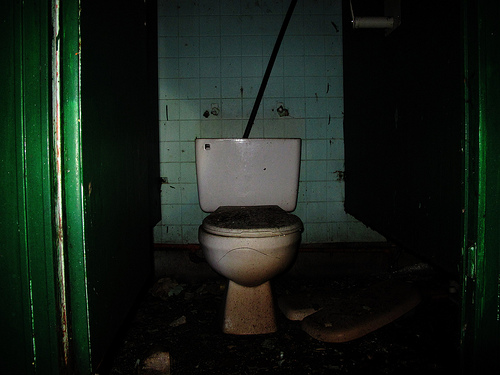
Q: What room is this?
A: It is a bathroom.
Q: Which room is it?
A: It is a bathroom.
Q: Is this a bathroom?
A: Yes, it is a bathroom.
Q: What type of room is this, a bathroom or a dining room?
A: It is a bathroom.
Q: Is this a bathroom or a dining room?
A: It is a bathroom.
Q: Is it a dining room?
A: No, it is a bathroom.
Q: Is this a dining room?
A: No, it is a bathroom.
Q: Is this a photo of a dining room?
A: No, the picture is showing a bathroom.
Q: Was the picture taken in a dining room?
A: No, the picture was taken in a bathroom.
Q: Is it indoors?
A: Yes, it is indoors.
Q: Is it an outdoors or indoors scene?
A: It is indoors.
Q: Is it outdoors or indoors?
A: It is indoors.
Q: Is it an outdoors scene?
A: No, it is indoors.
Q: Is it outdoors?
A: No, it is indoors.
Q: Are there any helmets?
A: No, there are no helmets.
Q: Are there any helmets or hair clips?
A: No, there are no helmets or hair clips.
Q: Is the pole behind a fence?
A: No, the pole is behind a toilet.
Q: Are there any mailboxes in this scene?
A: No, there are no mailboxes.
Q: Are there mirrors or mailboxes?
A: No, there are no mailboxes or mirrors.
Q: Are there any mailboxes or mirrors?
A: No, there are no mailboxes or mirrors.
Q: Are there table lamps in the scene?
A: No, there are no table lamps.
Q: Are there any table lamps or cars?
A: No, there are no table lamps or cars.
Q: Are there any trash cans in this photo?
A: No, there are no trash cans.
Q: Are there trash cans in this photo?
A: No, there are no trash cans.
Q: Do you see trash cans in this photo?
A: No, there are no trash cans.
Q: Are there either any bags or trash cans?
A: No, there are no trash cans or bags.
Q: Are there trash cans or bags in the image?
A: No, there are no trash cans or bags.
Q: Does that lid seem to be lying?
A: Yes, the lid is lying.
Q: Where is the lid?
A: The lid is on the floor.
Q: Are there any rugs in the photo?
A: No, there are no rugs.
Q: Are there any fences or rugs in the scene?
A: No, there are no rugs or fences.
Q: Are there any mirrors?
A: No, there are no mirrors.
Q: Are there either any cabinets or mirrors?
A: No, there are no mirrors or cabinets.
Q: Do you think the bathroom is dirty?
A: Yes, the bathroom is dirty.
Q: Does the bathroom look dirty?
A: Yes, the bathroom is dirty.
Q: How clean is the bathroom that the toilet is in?
A: The bathroom is dirty.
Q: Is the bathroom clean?
A: No, the bathroom is dirty.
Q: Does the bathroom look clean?
A: No, the bathroom is dirty.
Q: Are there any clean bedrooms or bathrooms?
A: No, there is a bathroom but it is dirty.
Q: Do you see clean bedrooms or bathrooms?
A: No, there is a bathroom but it is dirty.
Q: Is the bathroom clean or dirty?
A: The bathroom is dirty.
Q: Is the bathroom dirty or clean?
A: The bathroom is dirty.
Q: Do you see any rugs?
A: No, there are no rugs.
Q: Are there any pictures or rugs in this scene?
A: No, there are no rugs or pictures.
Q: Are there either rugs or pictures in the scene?
A: No, there are no rugs or pictures.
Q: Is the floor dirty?
A: Yes, the floor is dirty.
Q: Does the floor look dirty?
A: Yes, the floor is dirty.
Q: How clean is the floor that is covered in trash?
A: The floor is dirty.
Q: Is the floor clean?
A: No, the floor is dirty.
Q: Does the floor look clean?
A: No, the floor is dirty.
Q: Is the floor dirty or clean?
A: The floor is dirty.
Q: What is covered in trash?
A: The floor is covered in trash.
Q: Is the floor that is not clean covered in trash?
A: Yes, the floor is covered in trash.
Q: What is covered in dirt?
A: The floor is covered in dirt.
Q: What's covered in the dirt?
A: The floor is covered in dirt.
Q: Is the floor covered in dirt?
A: Yes, the floor is covered in dirt.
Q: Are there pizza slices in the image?
A: No, there are no pizza slices.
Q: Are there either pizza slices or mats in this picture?
A: No, there are no pizza slices or mats.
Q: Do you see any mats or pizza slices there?
A: No, there are no pizza slices or mats.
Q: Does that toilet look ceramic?
A: Yes, the toilet is ceramic.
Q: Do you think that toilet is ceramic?
A: Yes, the toilet is ceramic.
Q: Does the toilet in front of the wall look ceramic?
A: Yes, the toilet is ceramic.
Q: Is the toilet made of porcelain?
A: Yes, the toilet is made of porcelain.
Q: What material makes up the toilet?
A: The toilet is made of porcelain.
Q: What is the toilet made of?
A: The toilet is made of porcelain.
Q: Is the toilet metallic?
A: No, the toilet is ceramic.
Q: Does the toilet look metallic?
A: No, the toilet is ceramic.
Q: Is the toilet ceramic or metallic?
A: The toilet is ceramic.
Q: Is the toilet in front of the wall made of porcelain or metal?
A: The toilet is made of porcelain.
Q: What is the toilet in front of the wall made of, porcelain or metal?
A: The toilet is made of porcelain.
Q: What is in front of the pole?
A: The toilet is in front of the pole.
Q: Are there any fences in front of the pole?
A: No, there is a toilet in front of the pole.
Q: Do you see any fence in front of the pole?
A: No, there is a toilet in front of the pole.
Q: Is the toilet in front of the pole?
A: Yes, the toilet is in front of the pole.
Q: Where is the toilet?
A: The toilet is in the bathroom.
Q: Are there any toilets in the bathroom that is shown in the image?
A: Yes, there is a toilet in the bathroom.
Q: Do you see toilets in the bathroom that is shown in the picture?
A: Yes, there is a toilet in the bathroom.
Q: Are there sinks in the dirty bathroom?
A: No, there is a toilet in the bathroom.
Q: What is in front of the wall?
A: The toilet is in front of the wall.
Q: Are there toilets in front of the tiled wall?
A: Yes, there is a toilet in front of the wall.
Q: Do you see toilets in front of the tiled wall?
A: Yes, there is a toilet in front of the wall.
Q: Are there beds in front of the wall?
A: No, there is a toilet in front of the wall.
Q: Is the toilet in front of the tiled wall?
A: Yes, the toilet is in front of the wall.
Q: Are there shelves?
A: No, there are no shelves.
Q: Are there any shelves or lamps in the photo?
A: No, there are no shelves or lamps.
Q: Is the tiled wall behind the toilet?
A: Yes, the wall is behind the toilet.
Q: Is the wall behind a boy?
A: No, the wall is behind the toilet.